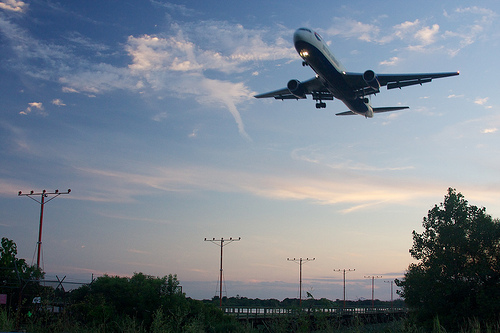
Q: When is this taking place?
A: Early evening.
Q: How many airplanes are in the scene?
A: One.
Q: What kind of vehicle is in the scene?
A: Airplane.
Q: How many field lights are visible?
A: Six.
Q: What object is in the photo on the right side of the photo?
A: Tree.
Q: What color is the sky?
A: Blue , white and pink.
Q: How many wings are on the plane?
A: Two.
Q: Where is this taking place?
A: Airport.